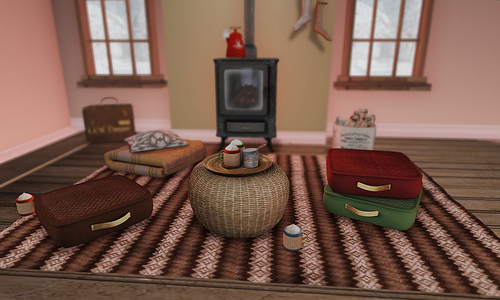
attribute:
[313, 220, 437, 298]
rug — green, Red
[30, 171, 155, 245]
suitcase — brown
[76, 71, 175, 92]
window sill — brown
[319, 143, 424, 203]
pillow — red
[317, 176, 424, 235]
pillow — green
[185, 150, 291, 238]
ottoman — brown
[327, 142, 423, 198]
suitcase — red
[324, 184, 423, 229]
container — red, green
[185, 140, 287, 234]
basket — large, brown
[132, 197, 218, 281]
stripe — white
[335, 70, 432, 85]
windowsill — brown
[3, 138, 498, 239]
hardwood floor — brown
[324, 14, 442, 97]
wooden frame — brown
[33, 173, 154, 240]
suitcase — brown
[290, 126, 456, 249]
containers — Red, green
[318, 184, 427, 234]
container — green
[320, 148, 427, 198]
container — red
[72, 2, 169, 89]
frame — brown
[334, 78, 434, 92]
window sill — brown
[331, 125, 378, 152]
box — white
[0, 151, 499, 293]
rug — striped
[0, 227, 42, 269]
stripe — white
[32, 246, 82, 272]
stripe — white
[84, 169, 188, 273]
stripe — white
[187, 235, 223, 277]
stripe — white